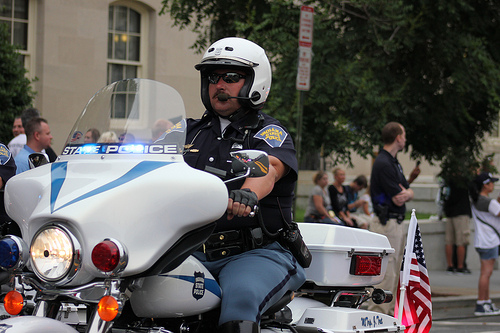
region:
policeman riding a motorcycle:
[28, 24, 365, 331]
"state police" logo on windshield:
[36, 96, 194, 206]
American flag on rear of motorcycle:
[378, 200, 440, 331]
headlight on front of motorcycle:
[16, 203, 96, 295]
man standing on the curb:
[359, 113, 429, 318]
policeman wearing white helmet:
[180, 21, 269, 130]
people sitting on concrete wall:
[306, 161, 395, 244]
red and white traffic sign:
[290, 4, 325, 179]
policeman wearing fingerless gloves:
[221, 169, 278, 236]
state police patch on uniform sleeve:
[246, 116, 303, 158]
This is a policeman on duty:
[194, 45, 289, 293]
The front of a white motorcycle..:
[20, 87, 190, 283]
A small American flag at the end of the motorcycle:
[398, 207, 435, 327]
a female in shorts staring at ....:
[474, 168, 497, 310]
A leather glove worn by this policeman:
[225, 182, 264, 219]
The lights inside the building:
[101, 25, 134, 54]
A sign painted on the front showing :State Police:
[44, 134, 189, 162]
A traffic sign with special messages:
[285, 8, 335, 101]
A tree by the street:
[334, 17, 495, 116]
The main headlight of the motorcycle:
[24, 223, 94, 279]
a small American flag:
[388, 207, 429, 331]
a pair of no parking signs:
[299, 12, 312, 95]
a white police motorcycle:
[7, 72, 404, 331]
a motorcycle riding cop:
[186, 34, 298, 331]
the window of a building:
[104, 4, 154, 122]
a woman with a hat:
[466, 165, 498, 325]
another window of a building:
[0, 0, 47, 117]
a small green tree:
[0, 32, 37, 149]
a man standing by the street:
[371, 105, 410, 297]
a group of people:
[310, 163, 377, 223]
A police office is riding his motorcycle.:
[160, 42, 345, 309]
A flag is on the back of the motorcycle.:
[398, 207, 442, 331]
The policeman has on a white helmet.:
[162, 33, 287, 123]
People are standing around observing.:
[365, 125, 494, 270]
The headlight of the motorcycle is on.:
[14, 213, 101, 307]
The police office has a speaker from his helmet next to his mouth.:
[210, 85, 288, 117]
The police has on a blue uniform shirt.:
[191, 110, 318, 252]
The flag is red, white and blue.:
[369, 207, 455, 331]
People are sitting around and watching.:
[308, 172, 380, 230]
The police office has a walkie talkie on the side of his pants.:
[271, 210, 338, 269]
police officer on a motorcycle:
[3, 29, 407, 328]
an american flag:
[395, 203, 437, 331]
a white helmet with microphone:
[202, 34, 276, 115]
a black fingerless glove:
[226, 185, 265, 229]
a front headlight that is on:
[29, 225, 86, 284]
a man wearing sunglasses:
[195, 42, 276, 119]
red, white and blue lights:
[1, 228, 130, 280]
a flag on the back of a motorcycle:
[377, 185, 444, 330]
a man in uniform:
[162, 22, 324, 332]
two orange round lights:
[5, 286, 123, 321]